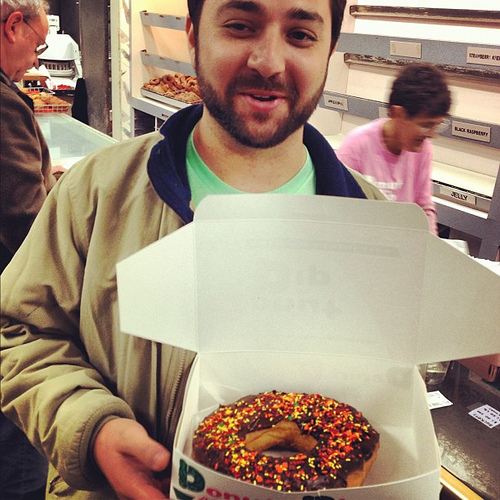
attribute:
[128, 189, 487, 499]
box — open, white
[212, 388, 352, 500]
donut — large, big, chocolate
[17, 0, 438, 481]
man — smiling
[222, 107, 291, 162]
bear — trim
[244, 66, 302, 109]
mustache — trim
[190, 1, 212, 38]
hair — dark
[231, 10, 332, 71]
eyes — open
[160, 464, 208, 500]
letters — green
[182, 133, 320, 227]
shirt — green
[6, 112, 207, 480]
jacket — brown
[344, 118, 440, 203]
shirt — pink